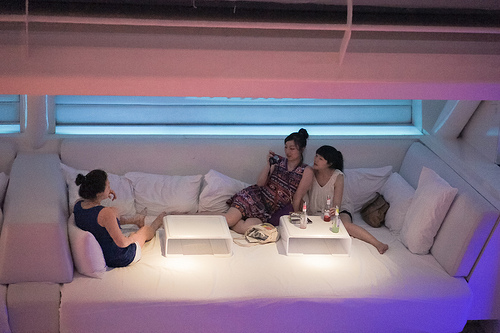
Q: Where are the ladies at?
A: Sofa bed.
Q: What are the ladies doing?
A: Taking pictures.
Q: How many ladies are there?
A: Three.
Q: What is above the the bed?
A: Window.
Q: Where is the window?
A: Above bed.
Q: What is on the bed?
A: Trays.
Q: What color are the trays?
A: White.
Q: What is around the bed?
A: Pillows.